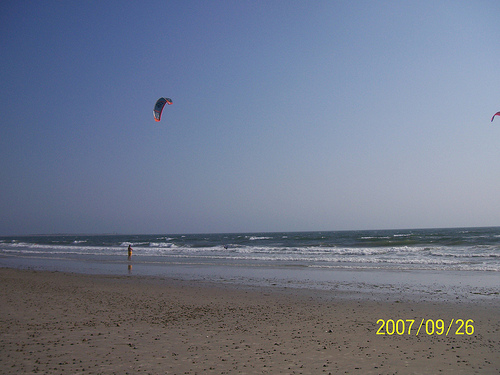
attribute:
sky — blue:
[13, 14, 498, 250]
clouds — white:
[309, 59, 384, 127]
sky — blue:
[286, 74, 431, 181]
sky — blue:
[199, 47, 466, 199]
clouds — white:
[67, 132, 124, 148]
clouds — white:
[390, 98, 454, 125]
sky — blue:
[30, 45, 455, 211]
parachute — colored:
[485, 98, 499, 125]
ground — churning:
[288, 77, 333, 117]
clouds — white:
[4, 135, 495, 226]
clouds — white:
[285, 117, 366, 200]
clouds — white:
[420, 101, 459, 162]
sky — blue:
[338, 13, 470, 98]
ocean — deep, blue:
[1, 225, 498, 269]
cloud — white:
[35, 137, 139, 199]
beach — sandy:
[0, 224, 499, 373]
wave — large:
[117, 239, 180, 253]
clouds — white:
[278, 120, 398, 289]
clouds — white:
[0, 0, 499, 235]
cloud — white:
[1, 61, 497, 233]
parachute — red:
[146, 90, 173, 122]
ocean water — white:
[1, 224, 495, 311]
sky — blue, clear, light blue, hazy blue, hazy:
[0, 0, 499, 228]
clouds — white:
[4, 1, 154, 84]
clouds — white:
[119, 1, 260, 59]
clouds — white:
[257, 0, 422, 60]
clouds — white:
[111, 1, 267, 65]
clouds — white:
[246, 0, 374, 65]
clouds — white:
[386, 0, 499, 70]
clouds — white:
[1, 2, 114, 78]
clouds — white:
[237, 0, 357, 49]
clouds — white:
[124, 0, 254, 55]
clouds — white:
[222, 0, 360, 55]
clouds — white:
[365, 1, 499, 61]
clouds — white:
[1, 0, 113, 69]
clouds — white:
[109, 0, 226, 66]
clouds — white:
[221, 0, 340, 64]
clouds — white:
[355, 1, 499, 72]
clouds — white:
[1, 1, 149, 95]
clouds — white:
[124, 2, 288, 73]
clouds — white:
[121, 1, 274, 65]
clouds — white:
[318, 0, 498, 70]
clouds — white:
[1, 0, 135, 75]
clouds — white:
[266, 1, 392, 59]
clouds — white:
[362, 0, 499, 66]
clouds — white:
[2, 0, 150, 78]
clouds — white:
[133, 2, 306, 68]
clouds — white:
[352, 2, 499, 58]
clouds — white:
[0, 0, 160, 72]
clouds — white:
[352, 0, 499, 82]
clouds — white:
[1, 1, 139, 66]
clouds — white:
[139, 0, 283, 62]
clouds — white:
[331, 2, 499, 74]